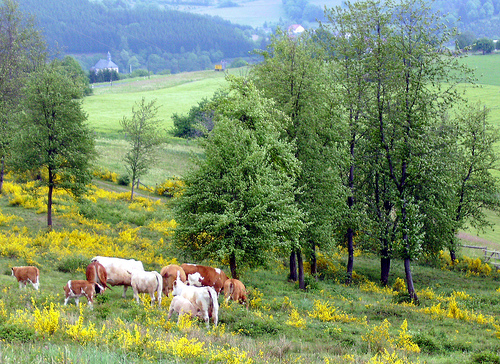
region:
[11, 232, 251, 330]
herd of cows in field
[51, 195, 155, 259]
yellow flowers in field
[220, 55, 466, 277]
group of green trees in field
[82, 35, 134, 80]
house with chimney in background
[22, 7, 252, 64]
hills and trees in background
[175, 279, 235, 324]
white cow in herd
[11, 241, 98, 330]
small brown and white cows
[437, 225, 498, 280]
metal gate with fence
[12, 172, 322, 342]
yellow flowered field with cows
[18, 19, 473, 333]
farm landscape with cows, trees and flowers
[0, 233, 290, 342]
Cows in a pasture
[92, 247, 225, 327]
Some all white cows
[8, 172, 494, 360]
Yellow weeds in the pasture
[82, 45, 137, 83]
A church in the background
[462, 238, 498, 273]
A fence along the road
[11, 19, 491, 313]
Trees in the pasture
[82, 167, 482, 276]
Road along side the field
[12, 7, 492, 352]
Photo taken during the day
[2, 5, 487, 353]
No people with the cows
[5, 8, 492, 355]
Picture taken during summer time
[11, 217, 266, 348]
a herd of cattle.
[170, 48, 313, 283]
a lush green tree.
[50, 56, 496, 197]
a field of green grass.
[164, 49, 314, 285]
a tree with lots of green leaves.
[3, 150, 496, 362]
a hillside covered in yellow flowers.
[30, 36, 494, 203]
a hillside covered in green grass.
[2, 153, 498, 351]
a bunch of wild flowers.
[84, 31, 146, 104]
a house at the bottom of a hill.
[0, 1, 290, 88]
a tree covered hillside.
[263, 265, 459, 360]
clusters of wild yellow flowers.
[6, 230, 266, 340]
cows walking in a field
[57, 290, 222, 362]
yellow flowers in the grass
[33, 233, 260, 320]
the cows are grazing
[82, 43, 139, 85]
a house in the distance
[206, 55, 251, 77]
a yellow vehicle in the background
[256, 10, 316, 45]
a house with a reddish roof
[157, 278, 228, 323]
2 white cows are standing in the grass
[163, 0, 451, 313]
a bunch of trees together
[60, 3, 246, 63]
dark green trees in the distance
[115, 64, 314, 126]
a field of bright green grass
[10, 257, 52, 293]
baby cow in the field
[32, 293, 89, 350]
yellow flowers in the field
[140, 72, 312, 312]
green tree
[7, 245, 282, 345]
bunch of cows together in a field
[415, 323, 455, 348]
green grass on the ground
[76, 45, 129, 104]
a house in the field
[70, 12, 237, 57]
green trees in the forest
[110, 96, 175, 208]
skinny green tree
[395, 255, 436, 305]
brown tree trunk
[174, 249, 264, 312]
dark brown cow eating from the field